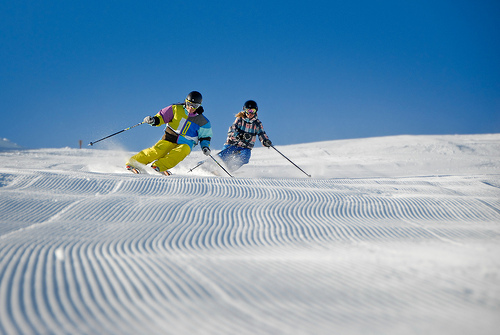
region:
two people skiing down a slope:
[52, 75, 347, 213]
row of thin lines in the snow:
[7, 227, 199, 327]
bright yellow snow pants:
[124, 138, 191, 173]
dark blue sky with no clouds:
[3, 5, 490, 140]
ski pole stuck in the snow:
[257, 140, 314, 179]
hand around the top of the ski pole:
[130, 99, 165, 136]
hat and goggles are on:
[179, 84, 209, 116]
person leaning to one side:
[109, 69, 229, 184]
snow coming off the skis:
[104, 143, 132, 169]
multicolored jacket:
[147, 101, 218, 152]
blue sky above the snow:
[293, 31, 358, 84]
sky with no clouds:
[320, 47, 375, 94]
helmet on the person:
[240, 92, 265, 122]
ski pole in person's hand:
[281, 143, 318, 178]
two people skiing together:
[123, 62, 294, 184]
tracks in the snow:
[140, 190, 222, 271]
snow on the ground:
[251, 198, 346, 283]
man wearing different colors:
[127, 92, 212, 197]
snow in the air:
[213, 147, 255, 182]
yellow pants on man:
[132, 144, 184, 184]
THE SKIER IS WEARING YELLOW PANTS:
[128, 138, 195, 178]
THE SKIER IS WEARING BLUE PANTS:
[213, 137, 256, 172]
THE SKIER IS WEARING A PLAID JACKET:
[217, 102, 274, 152]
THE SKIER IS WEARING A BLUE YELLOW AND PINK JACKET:
[141, 102, 216, 152]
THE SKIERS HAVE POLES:
[86, 115, 313, 187]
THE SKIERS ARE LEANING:
[123, 82, 270, 184]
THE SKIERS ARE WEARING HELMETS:
[183, 89, 261, 119]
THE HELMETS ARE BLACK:
[181, 82, 263, 125]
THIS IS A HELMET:
[181, 88, 203, 113]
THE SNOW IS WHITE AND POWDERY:
[0, 130, 499, 333]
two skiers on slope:
[124, 84, 312, 191]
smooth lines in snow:
[80, 229, 167, 301]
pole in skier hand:
[82, 117, 149, 155]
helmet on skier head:
[180, 85, 210, 110]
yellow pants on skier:
[137, 134, 193, 176]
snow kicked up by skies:
[97, 147, 134, 178]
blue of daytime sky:
[330, 29, 408, 82]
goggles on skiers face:
[177, 96, 203, 113]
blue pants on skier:
[215, 141, 261, 171]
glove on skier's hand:
[140, 109, 161, 130]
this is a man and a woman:
[115, 87, 291, 171]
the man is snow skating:
[127, 88, 225, 170]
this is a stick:
[206, 153, 228, 173]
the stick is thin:
[204, 151, 222, 175]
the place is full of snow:
[111, 206, 370, 324]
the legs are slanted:
[140, 140, 190, 163]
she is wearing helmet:
[246, 100, 256, 106]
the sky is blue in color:
[347, 10, 449, 98]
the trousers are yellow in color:
[148, 143, 186, 161]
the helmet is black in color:
[188, 90, 199, 98]